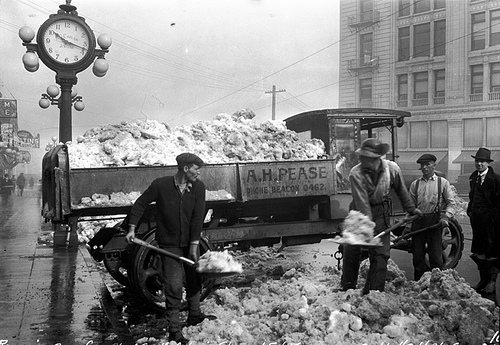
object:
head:
[177, 153, 200, 181]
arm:
[127, 179, 158, 224]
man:
[124, 152, 217, 344]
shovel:
[130, 235, 242, 277]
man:
[330, 137, 422, 297]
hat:
[354, 137, 390, 157]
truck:
[42, 108, 464, 312]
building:
[339, 0, 499, 204]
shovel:
[327, 213, 421, 247]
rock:
[381, 323, 403, 338]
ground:
[0, 185, 499, 344]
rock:
[279, 312, 291, 319]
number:
[67, 22, 71, 28]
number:
[64, 58, 71, 63]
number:
[319, 182, 325, 191]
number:
[302, 184, 309, 191]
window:
[412, 22, 428, 57]